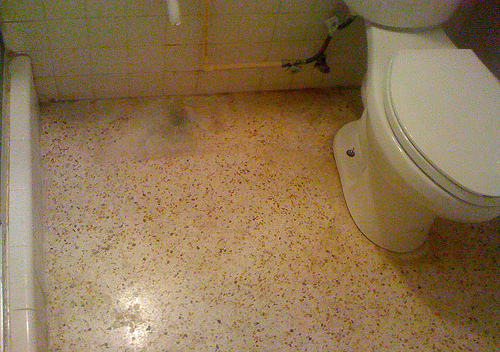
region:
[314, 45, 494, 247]
this is a toilet bowl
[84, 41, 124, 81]
this is a tile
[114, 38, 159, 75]
this is a tile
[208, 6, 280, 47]
this is a tile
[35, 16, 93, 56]
this is a tile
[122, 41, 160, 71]
this is a tile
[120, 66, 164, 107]
this is a tile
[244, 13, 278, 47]
this is a tile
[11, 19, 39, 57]
this is a tile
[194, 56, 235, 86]
this is a tile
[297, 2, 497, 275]
This is a toilet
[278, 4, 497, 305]
This is a toilet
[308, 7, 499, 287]
This is a toilet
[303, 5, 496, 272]
This is a toilet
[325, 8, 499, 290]
This is a toilet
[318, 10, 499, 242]
This is a toilet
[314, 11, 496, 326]
This is a toilet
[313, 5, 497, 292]
This is a toilet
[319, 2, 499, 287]
This is a toilet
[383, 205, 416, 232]
part of a shade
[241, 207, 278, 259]
part of a floor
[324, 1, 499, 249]
a white toilet in a bathroom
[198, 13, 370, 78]
a pluming line for a toilet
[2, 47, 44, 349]
the ledge of a shower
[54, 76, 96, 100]
white tile on a wall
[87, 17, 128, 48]
a white tile on a wall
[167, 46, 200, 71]
a white tile on a wall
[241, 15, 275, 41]
a white tile on a wall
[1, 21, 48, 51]
a white tile on a wall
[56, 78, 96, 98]
a white tile on a wall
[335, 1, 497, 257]
the toilet is white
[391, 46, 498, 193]
toilet lid is white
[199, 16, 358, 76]
pipe on the wall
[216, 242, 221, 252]
brown speck on the bathroom floor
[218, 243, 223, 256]
brown speck on the bathroom floor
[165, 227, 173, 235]
brown speck on the bathroom floor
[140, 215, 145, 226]
brown speck on the bathroom floor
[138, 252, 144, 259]
brown speck on the bathroom floor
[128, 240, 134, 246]
brown speck on the bathroom floor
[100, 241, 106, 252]
brown speck on the bathroom floor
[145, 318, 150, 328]
brown speck on the bathroom floor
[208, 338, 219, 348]
brown speck on the bathroom floor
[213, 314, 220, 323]
brown speck on the bathroom floor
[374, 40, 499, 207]
Toilet seat is closed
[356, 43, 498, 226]
Toilet seat is closed